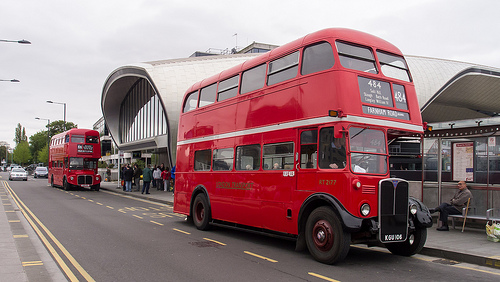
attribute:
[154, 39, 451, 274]
bus — red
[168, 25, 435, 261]
double decker — red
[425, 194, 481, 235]
pants — black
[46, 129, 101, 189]
bus — red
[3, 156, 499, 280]
road — dark, grey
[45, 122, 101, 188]
bus — red, double decker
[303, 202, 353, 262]
tire — black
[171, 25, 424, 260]
bus — double decker, red, double, checker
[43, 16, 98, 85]
sky — white, grey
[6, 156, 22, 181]
car — silver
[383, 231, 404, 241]
license — black, white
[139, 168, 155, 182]
jacket — green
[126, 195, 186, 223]
lettering — yellow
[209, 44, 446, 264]
bus — red, double decker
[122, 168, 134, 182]
jacket — black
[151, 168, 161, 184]
jacket — white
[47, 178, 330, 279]
markings — yellow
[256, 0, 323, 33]
clouds — thick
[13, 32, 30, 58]
lamp — street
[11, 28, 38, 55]
lamp — street